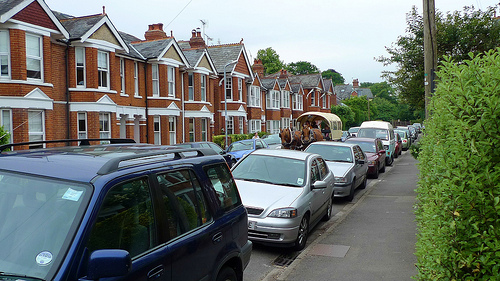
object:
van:
[358, 118, 402, 165]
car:
[346, 134, 389, 178]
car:
[301, 140, 373, 202]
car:
[213, 144, 340, 251]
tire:
[321, 191, 339, 224]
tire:
[289, 212, 314, 254]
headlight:
[266, 203, 298, 222]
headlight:
[330, 174, 348, 188]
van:
[0, 134, 258, 279]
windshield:
[358, 124, 391, 141]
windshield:
[0, 168, 96, 280]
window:
[201, 159, 246, 215]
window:
[155, 162, 217, 248]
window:
[69, 173, 166, 280]